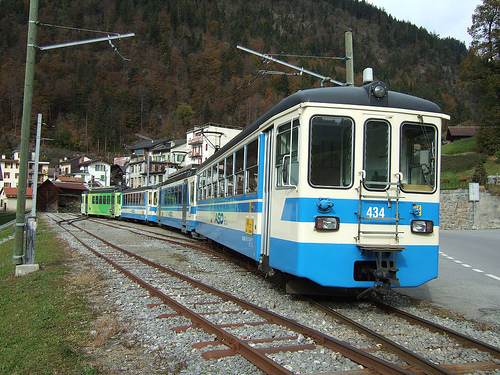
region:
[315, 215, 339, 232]
the headlights of a blue and beige train engine car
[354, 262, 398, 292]
the train coupling hitch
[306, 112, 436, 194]
the front windshield of a train car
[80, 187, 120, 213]
the last train car is green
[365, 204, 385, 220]
the number 434 is painted on the front of the train car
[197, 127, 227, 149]
the electric power roof contact line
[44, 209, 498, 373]
the steel railway tracks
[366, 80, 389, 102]
the train cars horn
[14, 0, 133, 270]
the electric power poles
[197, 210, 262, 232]
The letters ASO are written on the side of the car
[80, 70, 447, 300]
Train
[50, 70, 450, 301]
The train's compartments have different colors such as sky blue and green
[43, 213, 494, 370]
Train tracks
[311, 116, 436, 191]
Front windows of the train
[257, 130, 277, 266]
Train door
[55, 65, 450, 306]
The train is currently out of a tunnel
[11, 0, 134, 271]
Pole that contains electricity wires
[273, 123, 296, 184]
Side window of train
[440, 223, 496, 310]
Small section of a road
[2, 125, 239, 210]
Several buildings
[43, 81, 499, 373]
train is on tracks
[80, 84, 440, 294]
train is carrying people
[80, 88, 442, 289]
train has a lot of windows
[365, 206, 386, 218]
train has numbers on it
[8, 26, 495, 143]
trees behind the train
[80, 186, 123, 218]
last car is green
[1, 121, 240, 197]
buildings behind the train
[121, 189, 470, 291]
blue stripes on the train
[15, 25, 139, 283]
train is passing some poles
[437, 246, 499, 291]
white stripe on the street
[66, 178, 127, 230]
Green cart on the end of the train.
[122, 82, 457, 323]
Blue and white cars on the train.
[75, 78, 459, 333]
Train on the tracks.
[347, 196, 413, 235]
434 written on front of the train.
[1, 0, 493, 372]
Photo taken during the day.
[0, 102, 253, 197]
Group of houses in the background.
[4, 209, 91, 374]
Grass is green.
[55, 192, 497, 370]
Train tracks made of steel.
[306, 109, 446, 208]
Three windows in front of train.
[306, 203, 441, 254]
Headlights are off.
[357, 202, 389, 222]
Train identifier painted on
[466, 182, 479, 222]
Street sign on side of road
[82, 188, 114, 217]
Green boxcar on side of train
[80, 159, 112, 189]
White building inside a city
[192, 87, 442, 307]
Front car on passenger train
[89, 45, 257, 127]
Wooded hilly area on mountain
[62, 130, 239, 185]
Small country city skyline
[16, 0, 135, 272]
Electric train pole in city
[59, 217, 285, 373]
Train rail system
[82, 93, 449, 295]
Passenger train riding through the city